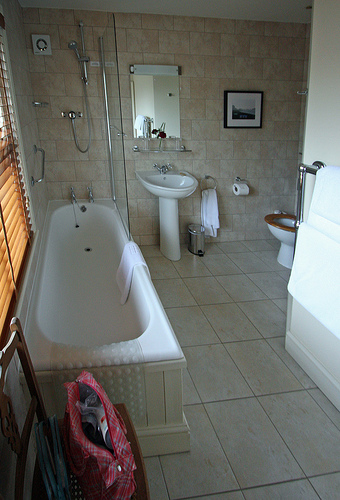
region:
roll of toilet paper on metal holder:
[231, 174, 250, 195]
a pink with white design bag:
[61, 366, 135, 496]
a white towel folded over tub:
[114, 238, 152, 301]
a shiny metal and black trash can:
[186, 221, 204, 255]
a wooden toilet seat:
[264, 209, 297, 230]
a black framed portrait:
[223, 86, 264, 129]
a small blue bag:
[34, 420, 65, 498]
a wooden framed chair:
[1, 316, 148, 498]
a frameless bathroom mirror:
[127, 61, 182, 141]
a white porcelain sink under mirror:
[134, 167, 197, 260]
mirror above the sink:
[128, 72, 181, 139]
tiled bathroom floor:
[196, 265, 281, 482]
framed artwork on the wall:
[221, 88, 263, 129]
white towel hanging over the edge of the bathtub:
[109, 241, 154, 304]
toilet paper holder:
[231, 176, 250, 195]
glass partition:
[95, 14, 133, 240]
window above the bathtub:
[0, 33, 30, 312]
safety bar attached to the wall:
[28, 145, 45, 185]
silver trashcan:
[186, 223, 205, 257]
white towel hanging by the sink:
[198, 175, 218, 237]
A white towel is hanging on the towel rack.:
[198, 172, 216, 235]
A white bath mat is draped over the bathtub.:
[112, 238, 146, 299]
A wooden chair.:
[0, 310, 149, 497]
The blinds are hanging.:
[0, 13, 34, 345]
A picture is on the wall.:
[221, 88, 260, 127]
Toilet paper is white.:
[228, 179, 245, 189]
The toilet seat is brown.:
[262, 210, 296, 227]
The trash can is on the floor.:
[187, 221, 205, 255]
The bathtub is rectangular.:
[20, 195, 190, 451]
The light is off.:
[128, 64, 183, 75]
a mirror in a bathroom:
[130, 63, 180, 139]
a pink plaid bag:
[61, 368, 141, 498]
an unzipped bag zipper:
[68, 376, 114, 460]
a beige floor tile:
[202, 394, 307, 488]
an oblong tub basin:
[39, 206, 149, 350]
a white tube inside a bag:
[95, 406, 109, 438]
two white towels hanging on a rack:
[286, 161, 337, 340]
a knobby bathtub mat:
[47, 340, 149, 430]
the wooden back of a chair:
[0, 319, 44, 498]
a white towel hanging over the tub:
[113, 240, 153, 301]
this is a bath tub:
[0, 188, 182, 392]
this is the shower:
[59, 14, 113, 179]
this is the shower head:
[58, 24, 92, 93]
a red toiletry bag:
[57, 365, 147, 498]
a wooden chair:
[1, 316, 184, 498]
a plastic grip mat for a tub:
[37, 329, 161, 434]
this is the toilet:
[257, 201, 306, 270]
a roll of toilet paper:
[226, 176, 255, 201]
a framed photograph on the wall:
[211, 71, 278, 136]